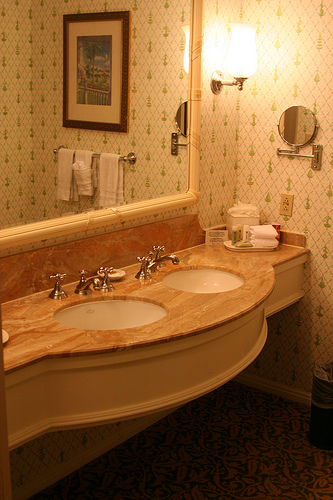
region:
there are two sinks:
[28, 220, 266, 338]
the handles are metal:
[39, 257, 119, 304]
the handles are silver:
[40, 251, 125, 309]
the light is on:
[219, 12, 263, 108]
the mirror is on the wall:
[260, 99, 327, 175]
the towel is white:
[85, 139, 132, 209]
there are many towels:
[40, 127, 130, 205]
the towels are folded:
[235, 220, 283, 261]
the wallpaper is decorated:
[275, 11, 313, 69]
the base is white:
[44, 364, 155, 416]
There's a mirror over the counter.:
[1, 2, 216, 246]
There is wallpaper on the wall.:
[200, 0, 332, 410]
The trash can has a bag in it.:
[302, 359, 331, 457]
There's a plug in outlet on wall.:
[273, 187, 305, 217]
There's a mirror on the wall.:
[264, 100, 326, 179]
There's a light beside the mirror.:
[208, 16, 258, 104]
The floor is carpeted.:
[26, 372, 331, 497]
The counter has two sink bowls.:
[1, 220, 317, 380]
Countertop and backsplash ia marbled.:
[0, 212, 318, 381]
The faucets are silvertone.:
[32, 241, 199, 297]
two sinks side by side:
[40, 234, 270, 366]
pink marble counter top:
[1, 198, 322, 418]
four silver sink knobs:
[43, 233, 201, 308]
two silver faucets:
[71, 246, 191, 307]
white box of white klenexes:
[223, 195, 265, 255]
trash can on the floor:
[296, 337, 328, 477]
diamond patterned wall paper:
[2, 2, 330, 489]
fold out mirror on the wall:
[267, 96, 328, 174]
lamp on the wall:
[206, 9, 271, 118]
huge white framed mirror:
[0, 2, 215, 267]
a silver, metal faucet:
[133, 243, 180, 280]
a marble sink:
[0, 211, 321, 373]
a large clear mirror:
[0, 1, 205, 250]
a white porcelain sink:
[46, 290, 174, 333]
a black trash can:
[307, 360, 331, 450]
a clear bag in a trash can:
[311, 359, 330, 408]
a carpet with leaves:
[12, 377, 331, 499]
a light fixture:
[278, 190, 294, 218]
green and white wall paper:
[277, 9, 323, 94]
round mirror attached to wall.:
[277, 103, 324, 170]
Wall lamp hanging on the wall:
[205, 17, 256, 93]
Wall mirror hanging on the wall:
[270, 101, 321, 168]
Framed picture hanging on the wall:
[56, 4, 130, 131]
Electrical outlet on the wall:
[274, 186, 291, 213]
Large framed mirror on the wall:
[0, 0, 203, 246]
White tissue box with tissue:
[221, 196, 255, 230]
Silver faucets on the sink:
[42, 261, 111, 298]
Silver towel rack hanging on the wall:
[46, 140, 132, 200]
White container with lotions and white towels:
[219, 221, 277, 248]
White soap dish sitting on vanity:
[95, 264, 124, 277]